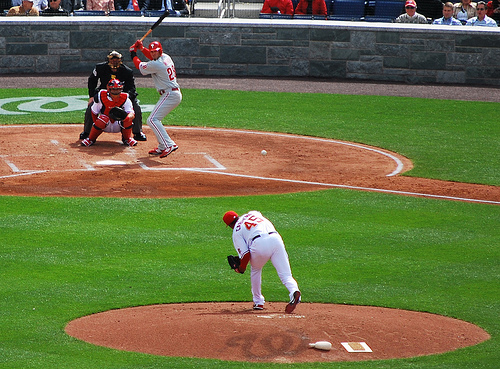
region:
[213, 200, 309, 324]
Pitcher wearing a white uniform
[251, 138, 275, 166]
Baseball in the air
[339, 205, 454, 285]
Green grass on the field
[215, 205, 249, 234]
Red hat on pitcher's head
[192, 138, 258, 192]
White lines on the dirt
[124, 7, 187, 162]
Baseball player holding a bat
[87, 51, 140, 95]
Umpire wearing black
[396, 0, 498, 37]
Three spectators watching game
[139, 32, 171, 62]
Red helmet on batter's head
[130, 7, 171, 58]
Black and brown baseball bat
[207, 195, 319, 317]
guy in uniform bending over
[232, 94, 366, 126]
green short field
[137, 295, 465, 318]
tan dirt on playing field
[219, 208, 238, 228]
guy with red hat on his head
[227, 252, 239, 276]
mitt in the hand of the guy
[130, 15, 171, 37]
brown and black bat in man's hand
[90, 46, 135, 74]
umpire in black clothes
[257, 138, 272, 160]
white baseball on dirt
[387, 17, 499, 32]
fans in the audience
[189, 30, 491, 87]
stone wall in front of players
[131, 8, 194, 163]
baseball player about to swing is bat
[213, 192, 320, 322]
a pitcher pitching a ball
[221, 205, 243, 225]
a red cap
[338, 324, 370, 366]
a white plate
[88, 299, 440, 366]
a pitcher's mound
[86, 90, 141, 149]
a catcher's white and white uniform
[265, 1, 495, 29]
spectators watching a baseball game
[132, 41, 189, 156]
a baseball player wearing a white and red uniform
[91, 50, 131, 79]
an umpire wearing all black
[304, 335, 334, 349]
a plastic bottle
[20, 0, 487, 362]
Photo taken at a baseball game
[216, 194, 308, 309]
Man pitching a baseball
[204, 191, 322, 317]
The pitcher's number is 45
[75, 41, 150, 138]
Umpire standing behind the catcher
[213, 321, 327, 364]
W on the pitcher's mound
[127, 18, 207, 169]
The batter is right handed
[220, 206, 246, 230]
Red hat on the pitcher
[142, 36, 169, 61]
Red helmet on the catcher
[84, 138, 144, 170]
Home plate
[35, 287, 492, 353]
The pitcher's mound is dirt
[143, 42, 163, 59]
batter has red hat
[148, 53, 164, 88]
batter has grey shirt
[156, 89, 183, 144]
batter has grey pants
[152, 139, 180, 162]
batter has red shoes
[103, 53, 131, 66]
umpire is wearing mask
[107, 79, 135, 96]
catcher has black helmet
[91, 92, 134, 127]
catcher has red chest guard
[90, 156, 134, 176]
home plate is white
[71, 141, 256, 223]
infield dirt is reddish-brown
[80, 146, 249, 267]
infield grass is short and green